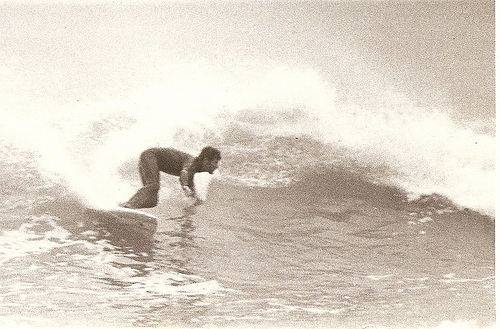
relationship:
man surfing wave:
[127, 146, 222, 209] [2, 2, 492, 324]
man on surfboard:
[127, 146, 222, 209] [89, 199, 159, 242]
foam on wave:
[0, 70, 495, 215] [8, 88, 484, 307]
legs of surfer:
[127, 149, 159, 209] [122, 138, 222, 218]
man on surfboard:
[127, 146, 222, 209] [94, 192, 159, 225]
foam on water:
[0, 213, 232, 325] [1, 203, 496, 326]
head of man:
[198, 145, 220, 175] [127, 146, 222, 209]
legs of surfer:
[125, 172, 171, 226] [107, 144, 171, 209]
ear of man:
[196, 155, 208, 166] [127, 146, 222, 209]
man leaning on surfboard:
[127, 146, 222, 209] [109, 204, 161, 229]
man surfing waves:
[127, 146, 222, 209] [5, 41, 498, 223]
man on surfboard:
[127, 146, 222, 209] [86, 204, 161, 251]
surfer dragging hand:
[118, 145, 221, 208] [170, 177, 261, 215]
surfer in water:
[118, 145, 221, 208] [66, 119, 493, 299]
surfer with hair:
[118, 145, 221, 208] [198, 144, 220, 160]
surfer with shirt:
[118, 145, 221, 208] [159, 146, 199, 191]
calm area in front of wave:
[202, 181, 474, 311] [25, 60, 485, 321]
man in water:
[127, 146, 222, 209] [3, 2, 499, 326]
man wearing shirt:
[127, 142, 227, 215] [159, 147, 199, 189]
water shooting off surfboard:
[35, 129, 123, 204] [16, 140, 221, 269]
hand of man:
[187, 189, 207, 206] [127, 146, 222, 209]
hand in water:
[187, 189, 207, 206] [1, 49, 498, 327]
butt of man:
[139, 146, 153, 171] [121, 140, 224, 225]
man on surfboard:
[127, 146, 222, 209] [98, 206, 161, 236]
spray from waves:
[12, 2, 497, 175] [2, 0, 496, 215]